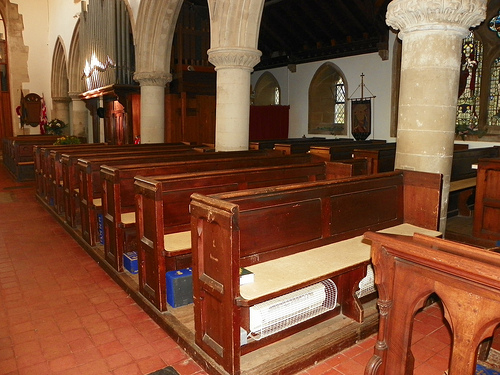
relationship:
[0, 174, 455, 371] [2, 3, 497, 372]
floor of building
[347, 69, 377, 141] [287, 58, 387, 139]
banner on wall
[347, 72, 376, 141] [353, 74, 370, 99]
banner on top of cross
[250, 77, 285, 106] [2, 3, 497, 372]
arch inside building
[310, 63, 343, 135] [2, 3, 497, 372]
arch inside building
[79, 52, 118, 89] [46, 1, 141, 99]
light on wall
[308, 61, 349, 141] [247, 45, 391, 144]
window on wall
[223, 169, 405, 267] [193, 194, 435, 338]
panels on back rest of seat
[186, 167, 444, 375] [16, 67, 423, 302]
bench in place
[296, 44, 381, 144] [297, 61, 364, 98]
window with arch